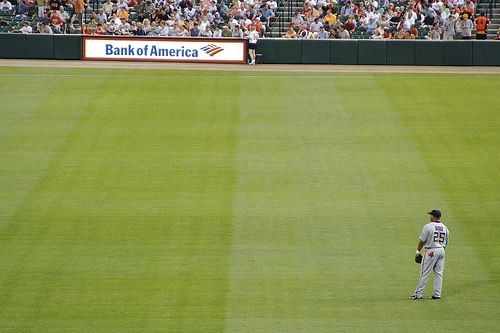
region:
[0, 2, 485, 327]
man on baseball field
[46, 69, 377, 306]
baseball field is green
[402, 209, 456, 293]
baseball player wearing grey uniform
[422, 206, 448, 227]
baseball player wearing black hat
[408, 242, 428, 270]
baseball player wear catchers mit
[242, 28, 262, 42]
person wearing white shirt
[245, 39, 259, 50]
person wearing black shorts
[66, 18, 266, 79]
white sign on fence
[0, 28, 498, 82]
fence is dark green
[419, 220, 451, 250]
red writing on jersey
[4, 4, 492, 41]
Spectators watching a baseball game.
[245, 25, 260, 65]
A person wearing black shorts.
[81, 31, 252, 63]
A long square sign.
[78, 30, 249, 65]
A red, white and blue sign.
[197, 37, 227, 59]
Logo for Bank of America.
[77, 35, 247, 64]
Advertisement for Bank of America.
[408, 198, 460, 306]
A baseball player standing in the field.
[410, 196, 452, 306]
Baseball player wearing a team uniform.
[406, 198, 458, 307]
Baseball player with glove on left hand.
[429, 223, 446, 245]
The number 25 on player's shirt.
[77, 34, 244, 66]
a "Bank of America" sign on the wall of a baseball field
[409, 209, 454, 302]
a baseball play standing the outfield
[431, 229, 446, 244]
a black number on the back of a baseball jersey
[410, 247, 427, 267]
a baseball glove on a hand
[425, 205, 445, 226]
the head of a baseball player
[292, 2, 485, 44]
a crowd of a fans in the stadium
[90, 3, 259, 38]
a crowd of a fans in the stadium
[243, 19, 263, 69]
a person standing on the edge of a baseball field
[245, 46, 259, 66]
the legs of a person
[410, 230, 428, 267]
thhe arm of a baseball player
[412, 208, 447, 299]
baseball player standing on grass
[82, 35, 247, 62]
white banner hanging on a green wall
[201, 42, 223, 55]
logo on banner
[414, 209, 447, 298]
baseball player wearing a dark cap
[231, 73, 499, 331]
light green stripe next to dark green stripe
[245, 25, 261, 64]
person standing near the banner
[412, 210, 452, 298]
baseball player wearing black glove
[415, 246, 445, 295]
gray pants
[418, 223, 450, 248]
gray jersey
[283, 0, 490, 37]
crowd sitting in the stands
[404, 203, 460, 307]
base ball player in a grey uniform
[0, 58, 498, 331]
large section of grassy green base ball field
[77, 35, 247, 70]
red white and blue bank of america advertisement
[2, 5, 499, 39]
large group of base ball fans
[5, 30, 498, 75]
protective green padded fence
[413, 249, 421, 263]
black leather base ball glove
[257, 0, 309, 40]
grey and green stairs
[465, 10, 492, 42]
person in a bright orange shirt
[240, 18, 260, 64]
person wearing a white tee shirt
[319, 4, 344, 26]
person in a bright yellow shirt